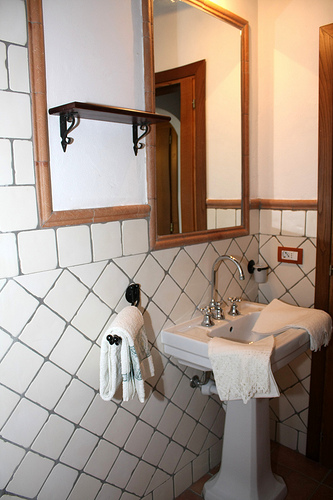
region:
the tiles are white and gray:
[30, 372, 117, 456]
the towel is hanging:
[76, 343, 200, 445]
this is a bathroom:
[0, 0, 329, 494]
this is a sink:
[147, 234, 325, 497]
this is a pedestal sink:
[158, 227, 313, 497]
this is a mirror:
[130, 0, 286, 257]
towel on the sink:
[223, 274, 325, 403]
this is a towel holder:
[78, 273, 147, 348]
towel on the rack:
[83, 290, 162, 407]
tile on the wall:
[9, 231, 228, 492]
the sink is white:
[173, 245, 319, 472]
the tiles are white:
[25, 336, 85, 439]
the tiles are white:
[22, 348, 106, 468]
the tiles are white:
[4, 371, 99, 461]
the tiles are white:
[13, 356, 89, 482]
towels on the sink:
[235, 293, 331, 384]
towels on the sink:
[219, 307, 316, 420]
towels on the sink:
[213, 310, 321, 425]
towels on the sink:
[196, 277, 331, 433]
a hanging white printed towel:
[98, 304, 155, 404]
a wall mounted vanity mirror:
[141, 0, 252, 249]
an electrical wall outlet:
[275, 245, 303, 264]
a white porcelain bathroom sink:
[160, 298, 320, 372]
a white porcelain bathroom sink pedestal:
[200, 397, 286, 497]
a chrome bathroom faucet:
[209, 252, 245, 319]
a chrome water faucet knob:
[198, 304, 214, 327]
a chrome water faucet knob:
[226, 294, 241, 316]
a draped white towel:
[208, 334, 280, 402]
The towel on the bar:
[98, 312, 160, 399]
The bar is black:
[105, 334, 123, 344]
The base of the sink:
[211, 396, 272, 496]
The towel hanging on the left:
[205, 334, 276, 406]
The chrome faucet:
[206, 249, 245, 297]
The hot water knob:
[199, 306, 216, 325]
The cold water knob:
[225, 294, 245, 314]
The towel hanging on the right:
[255, 297, 332, 362]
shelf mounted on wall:
[48, 97, 170, 154]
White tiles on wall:
[25, 408, 137, 486]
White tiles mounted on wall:
[49, 410, 175, 476]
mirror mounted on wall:
[142, 0, 249, 236]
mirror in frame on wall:
[141, 0, 251, 248]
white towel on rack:
[99, 306, 155, 407]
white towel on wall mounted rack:
[98, 283, 156, 403]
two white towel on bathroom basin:
[209, 297, 332, 400]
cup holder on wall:
[246, 258, 270, 285]